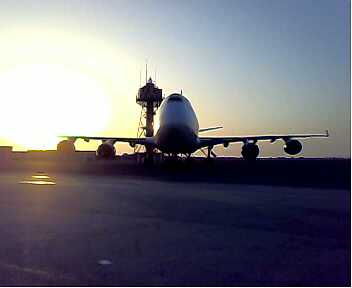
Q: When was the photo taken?
A: Morning.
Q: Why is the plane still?
A: Parked.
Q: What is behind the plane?
A: Tower.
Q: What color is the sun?
A: Yellow.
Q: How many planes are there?
A: One.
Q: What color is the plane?
A: White.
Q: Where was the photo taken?
A: Runway.